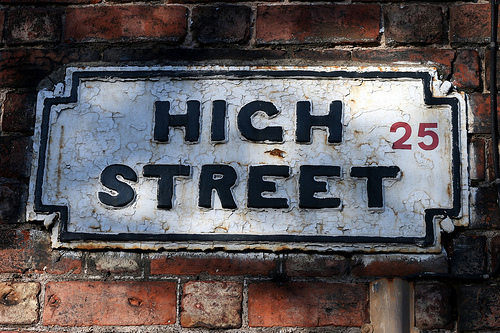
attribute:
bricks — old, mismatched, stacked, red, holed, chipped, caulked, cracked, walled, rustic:
[0, 1, 497, 329]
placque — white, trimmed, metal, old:
[19, 57, 474, 263]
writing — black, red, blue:
[95, 86, 447, 231]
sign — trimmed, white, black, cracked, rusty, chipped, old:
[20, 62, 492, 250]